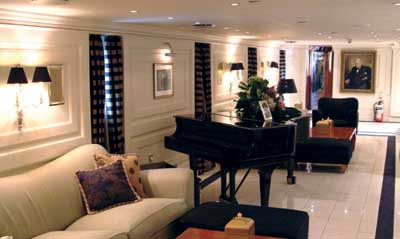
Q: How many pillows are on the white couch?
A: 2.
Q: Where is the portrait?
A: Back wall.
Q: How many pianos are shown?
A: 1.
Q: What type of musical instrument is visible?
A: Piano.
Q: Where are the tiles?
A: Floor.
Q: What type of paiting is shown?
A: Portrait.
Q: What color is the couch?
A: White.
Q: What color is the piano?
A: Black.